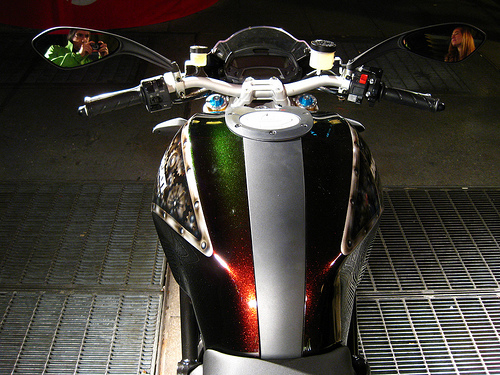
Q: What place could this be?
A: It is a street.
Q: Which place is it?
A: It is a street.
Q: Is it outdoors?
A: Yes, it is outdoors.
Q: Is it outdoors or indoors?
A: It is outdoors.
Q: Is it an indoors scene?
A: No, it is outdoors.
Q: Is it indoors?
A: No, it is outdoors.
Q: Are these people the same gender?
A: No, they are both male and female.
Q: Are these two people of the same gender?
A: No, they are both male and female.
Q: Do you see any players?
A: No, there are no players.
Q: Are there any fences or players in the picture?
A: No, there are no players or fences.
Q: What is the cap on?
A: The cap is on the motorbike.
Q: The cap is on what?
A: The cap is on the motorbike.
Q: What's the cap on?
A: The cap is on the motorbike.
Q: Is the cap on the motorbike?
A: Yes, the cap is on the motorbike.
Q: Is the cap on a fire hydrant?
A: No, the cap is on the motorbike.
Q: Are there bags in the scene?
A: No, there are no bags.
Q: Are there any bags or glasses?
A: No, there are no bags or glasses.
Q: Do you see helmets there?
A: No, there are no helmets.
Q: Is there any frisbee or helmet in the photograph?
A: No, there are no helmets or frisbees.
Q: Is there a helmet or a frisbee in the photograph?
A: No, there are no helmets or frisbees.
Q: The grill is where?
A: The grill is on the street.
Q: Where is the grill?
A: The grill is on the street.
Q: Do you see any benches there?
A: No, there are no benches.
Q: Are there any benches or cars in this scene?
A: No, there are no benches or cars.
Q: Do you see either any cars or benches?
A: No, there are no benches or cars.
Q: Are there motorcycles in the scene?
A: Yes, there is a motorcycle.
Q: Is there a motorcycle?
A: Yes, there is a motorcycle.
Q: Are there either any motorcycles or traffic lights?
A: Yes, there is a motorcycle.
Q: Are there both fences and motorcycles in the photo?
A: No, there is a motorcycle but no fences.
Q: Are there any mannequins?
A: No, there are no mannequins.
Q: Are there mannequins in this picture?
A: No, there are no mannequins.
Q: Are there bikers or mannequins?
A: No, there are no mannequins or bikers.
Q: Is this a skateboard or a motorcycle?
A: This is a motorcycle.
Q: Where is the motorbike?
A: The motorbike is on the street.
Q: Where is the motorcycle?
A: The motorbike is on the street.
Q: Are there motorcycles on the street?
A: Yes, there is a motorcycle on the street.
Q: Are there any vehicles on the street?
A: No, there is a motorcycle on the street.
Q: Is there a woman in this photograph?
A: Yes, there is a woman.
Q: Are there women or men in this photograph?
A: Yes, there is a woman.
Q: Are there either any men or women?
A: Yes, there is a woman.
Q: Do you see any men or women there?
A: Yes, there is a woman.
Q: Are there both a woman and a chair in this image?
A: No, there is a woman but no chairs.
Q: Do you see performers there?
A: No, there are no performers.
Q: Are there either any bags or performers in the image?
A: No, there are no performers or bags.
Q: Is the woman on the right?
A: Yes, the woman is on the right of the image.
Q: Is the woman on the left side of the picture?
A: No, the woman is on the right of the image.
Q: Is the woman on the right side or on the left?
A: The woman is on the right of the image.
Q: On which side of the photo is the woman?
A: The woman is on the right of the image.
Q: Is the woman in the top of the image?
A: Yes, the woman is in the top of the image.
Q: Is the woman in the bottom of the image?
A: No, the woman is in the top of the image.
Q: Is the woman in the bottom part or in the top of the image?
A: The woman is in the top of the image.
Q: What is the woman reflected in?
A: The woman is reflected in the mirror.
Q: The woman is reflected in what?
A: The woman is reflected in the mirror.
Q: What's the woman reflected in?
A: The woman is reflected in the mirror.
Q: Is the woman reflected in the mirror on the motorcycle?
A: Yes, the woman is reflected in the mirror.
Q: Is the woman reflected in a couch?
A: No, the woman is reflected in the mirror.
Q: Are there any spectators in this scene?
A: No, there are no spectators.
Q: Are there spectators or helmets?
A: No, there are no spectators or helmets.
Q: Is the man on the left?
A: Yes, the man is on the left of the image.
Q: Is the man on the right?
A: No, the man is on the left of the image.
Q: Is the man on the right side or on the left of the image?
A: The man is on the left of the image.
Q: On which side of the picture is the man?
A: The man is on the left of the image.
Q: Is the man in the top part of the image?
A: Yes, the man is in the top of the image.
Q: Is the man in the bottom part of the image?
A: No, the man is in the top of the image.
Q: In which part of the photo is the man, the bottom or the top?
A: The man is in the top of the image.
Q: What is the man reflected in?
A: The man is reflected in the mirror.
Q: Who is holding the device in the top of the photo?
A: The man is holding the camera.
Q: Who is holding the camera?
A: The man is holding the camera.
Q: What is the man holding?
A: The man is holding the camera.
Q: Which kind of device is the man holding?
A: The man is holding the camera.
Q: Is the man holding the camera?
A: Yes, the man is holding the camera.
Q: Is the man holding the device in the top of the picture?
A: Yes, the man is holding the camera.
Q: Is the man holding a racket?
A: No, the man is holding the camera.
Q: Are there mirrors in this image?
A: Yes, there is a mirror.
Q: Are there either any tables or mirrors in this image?
A: Yes, there is a mirror.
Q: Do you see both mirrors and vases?
A: No, there is a mirror but no vases.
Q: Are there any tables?
A: No, there are no tables.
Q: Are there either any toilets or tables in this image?
A: No, there are no tables or toilets.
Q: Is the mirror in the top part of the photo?
A: Yes, the mirror is in the top of the image.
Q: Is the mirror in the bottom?
A: No, the mirror is in the top of the image.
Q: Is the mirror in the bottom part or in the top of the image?
A: The mirror is in the top of the image.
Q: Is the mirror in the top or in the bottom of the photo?
A: The mirror is in the top of the image.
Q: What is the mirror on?
A: The mirror is on the motorbike.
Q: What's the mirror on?
A: The mirror is on the motorbike.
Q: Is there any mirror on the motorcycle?
A: Yes, there is a mirror on the motorcycle.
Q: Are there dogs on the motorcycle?
A: No, there is a mirror on the motorcycle.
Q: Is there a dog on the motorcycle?
A: No, there is a mirror on the motorcycle.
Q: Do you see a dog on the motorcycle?
A: No, there is a mirror on the motorcycle.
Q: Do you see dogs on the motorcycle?
A: No, there is a mirror on the motorcycle.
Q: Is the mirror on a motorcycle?
A: Yes, the mirror is on a motorcycle.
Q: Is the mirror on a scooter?
A: No, the mirror is on a motorcycle.